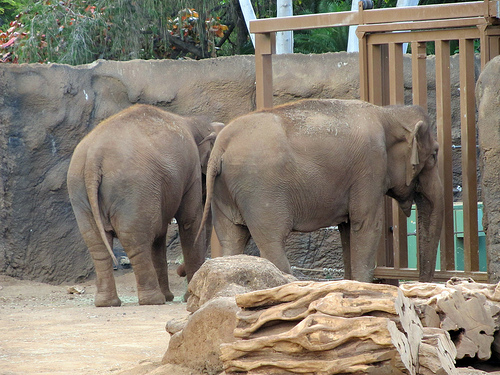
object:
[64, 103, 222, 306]
elephant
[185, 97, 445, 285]
elephant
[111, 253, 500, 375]
log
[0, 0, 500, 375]
cage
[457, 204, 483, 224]
water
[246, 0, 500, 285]
fence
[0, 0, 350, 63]
grass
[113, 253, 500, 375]
rock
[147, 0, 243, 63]
tree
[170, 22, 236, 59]
trunk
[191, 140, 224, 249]
tail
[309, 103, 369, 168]
skin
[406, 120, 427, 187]
ear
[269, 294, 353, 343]
plank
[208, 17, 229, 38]
fruit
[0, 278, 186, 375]
sand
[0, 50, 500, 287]
wall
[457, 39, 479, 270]
post